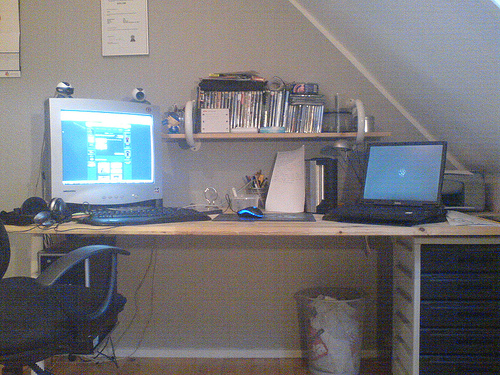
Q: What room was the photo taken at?
A: It was taken at the office.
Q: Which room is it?
A: It is an office.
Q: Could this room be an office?
A: Yes, it is an office.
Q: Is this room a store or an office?
A: It is an office.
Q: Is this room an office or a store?
A: It is an office.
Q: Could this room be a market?
A: No, it is an office.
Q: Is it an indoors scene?
A: Yes, it is indoors.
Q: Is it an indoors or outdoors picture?
A: It is indoors.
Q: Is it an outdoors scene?
A: No, it is indoors.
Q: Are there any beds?
A: No, there are no beds.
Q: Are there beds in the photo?
A: No, there are no beds.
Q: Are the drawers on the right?
A: Yes, the drawers are on the right of the image.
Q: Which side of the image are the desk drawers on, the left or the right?
A: The drawers are on the right of the image.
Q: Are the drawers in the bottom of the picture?
A: Yes, the drawers are in the bottom of the image.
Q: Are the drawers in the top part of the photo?
A: No, the drawers are in the bottom of the image.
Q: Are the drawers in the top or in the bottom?
A: The drawers are in the bottom of the image.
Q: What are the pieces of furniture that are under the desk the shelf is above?
A: The pieces of furniture are drawers.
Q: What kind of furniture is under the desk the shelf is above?
A: The pieces of furniture are drawers.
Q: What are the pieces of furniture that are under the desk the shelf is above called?
A: The pieces of furniture are drawers.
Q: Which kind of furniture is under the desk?
A: The pieces of furniture are drawers.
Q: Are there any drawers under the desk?
A: Yes, there are drawers under the desk.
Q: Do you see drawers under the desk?
A: Yes, there are drawers under the desk.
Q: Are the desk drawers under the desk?
A: Yes, the drawers are under the desk.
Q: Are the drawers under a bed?
A: No, the drawers are under the desk.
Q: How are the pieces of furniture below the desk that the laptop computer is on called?
A: The pieces of furniture are drawers.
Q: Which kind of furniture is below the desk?
A: The pieces of furniture are drawers.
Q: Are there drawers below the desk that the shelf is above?
A: Yes, there are drawers below the desk.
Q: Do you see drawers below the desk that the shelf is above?
A: Yes, there are drawers below the desk.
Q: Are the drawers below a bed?
A: No, the drawers are below the desk.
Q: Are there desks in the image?
A: Yes, there is a desk.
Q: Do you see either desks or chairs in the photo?
A: Yes, there is a desk.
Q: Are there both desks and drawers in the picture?
A: Yes, there are both a desk and drawers.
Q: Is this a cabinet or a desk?
A: This is a desk.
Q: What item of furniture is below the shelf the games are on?
A: The piece of furniture is a desk.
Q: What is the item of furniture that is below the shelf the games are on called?
A: The piece of furniture is a desk.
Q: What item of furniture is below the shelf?
A: The piece of furniture is a desk.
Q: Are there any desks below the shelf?
A: Yes, there is a desk below the shelf.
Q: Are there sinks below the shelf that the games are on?
A: No, there is a desk below the shelf.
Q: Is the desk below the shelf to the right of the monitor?
A: Yes, the desk is below the shelf.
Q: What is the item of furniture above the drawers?
A: The piece of furniture is a desk.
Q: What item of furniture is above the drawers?
A: The piece of furniture is a desk.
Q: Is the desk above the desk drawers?
A: Yes, the desk is above the drawers.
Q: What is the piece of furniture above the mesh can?
A: The piece of furniture is a desk.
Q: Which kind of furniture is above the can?
A: The piece of furniture is a desk.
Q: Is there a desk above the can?
A: Yes, there is a desk above the can.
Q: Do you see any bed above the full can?
A: No, there is a desk above the can.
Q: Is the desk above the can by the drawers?
A: Yes, the desk is above the can.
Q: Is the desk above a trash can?
A: No, the desk is above the can.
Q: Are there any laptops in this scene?
A: Yes, there is a laptop.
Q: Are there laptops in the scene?
A: Yes, there is a laptop.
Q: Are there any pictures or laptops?
A: Yes, there is a laptop.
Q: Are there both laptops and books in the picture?
A: No, there is a laptop but no books.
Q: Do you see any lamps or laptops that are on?
A: Yes, the laptop is on.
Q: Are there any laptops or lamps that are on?
A: Yes, the laptop is on.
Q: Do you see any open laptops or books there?
A: Yes, there is an open laptop.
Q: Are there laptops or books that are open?
A: Yes, the laptop is open.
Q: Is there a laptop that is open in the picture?
A: Yes, there is an open laptop.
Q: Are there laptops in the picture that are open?
A: Yes, there is a laptop that is open.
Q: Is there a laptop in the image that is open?
A: Yes, there is a laptop that is open.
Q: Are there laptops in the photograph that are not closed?
A: Yes, there is a open laptop.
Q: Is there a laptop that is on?
A: Yes, there is a laptop that is on.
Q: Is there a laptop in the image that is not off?
A: Yes, there is a laptop that is on.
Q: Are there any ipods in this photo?
A: No, there are no ipods.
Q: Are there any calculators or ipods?
A: No, there are no ipods or calculators.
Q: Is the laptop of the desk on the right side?
A: Yes, the laptop is on the right of the image.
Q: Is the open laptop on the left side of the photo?
A: No, the laptop is on the right of the image.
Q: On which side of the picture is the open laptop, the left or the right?
A: The laptop computer is on the right of the image.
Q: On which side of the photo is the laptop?
A: The laptop is on the right of the image.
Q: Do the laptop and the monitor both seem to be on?
A: Yes, both the laptop and the monitor are on.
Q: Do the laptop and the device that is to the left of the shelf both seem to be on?
A: Yes, both the laptop and the monitor are on.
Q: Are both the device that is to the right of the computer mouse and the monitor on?
A: Yes, both the laptop and the monitor are on.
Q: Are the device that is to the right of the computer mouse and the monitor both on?
A: Yes, both the laptop and the monitor are on.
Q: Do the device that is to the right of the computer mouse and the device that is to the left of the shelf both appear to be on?
A: Yes, both the laptop and the monitor are on.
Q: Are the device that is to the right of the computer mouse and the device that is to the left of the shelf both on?
A: Yes, both the laptop and the monitor are on.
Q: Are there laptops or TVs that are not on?
A: No, there is a laptop but it is on.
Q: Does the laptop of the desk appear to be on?
A: Yes, the laptop is on.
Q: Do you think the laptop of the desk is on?
A: Yes, the laptop is on.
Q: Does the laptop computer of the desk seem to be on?
A: Yes, the laptop is on.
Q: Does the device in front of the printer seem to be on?
A: Yes, the laptop is on.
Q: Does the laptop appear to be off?
A: No, the laptop is on.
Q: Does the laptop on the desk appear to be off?
A: No, the laptop is on.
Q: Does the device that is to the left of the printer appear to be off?
A: No, the laptop is on.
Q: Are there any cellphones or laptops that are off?
A: No, there is a laptop but it is on.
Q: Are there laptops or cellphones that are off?
A: No, there is a laptop but it is on.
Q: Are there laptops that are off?
A: No, there is a laptop but it is on.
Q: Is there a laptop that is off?
A: No, there is a laptop but it is on.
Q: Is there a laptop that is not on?
A: No, there is a laptop but it is on.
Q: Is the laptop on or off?
A: The laptop is on.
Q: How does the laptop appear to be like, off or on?
A: The laptop is on.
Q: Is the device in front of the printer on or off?
A: The laptop is on.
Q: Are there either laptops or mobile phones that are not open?
A: No, there is a laptop but it is open.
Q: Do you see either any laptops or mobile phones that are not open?
A: No, there is a laptop but it is open.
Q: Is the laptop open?
A: Yes, the laptop is open.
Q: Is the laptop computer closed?
A: No, the laptop computer is open.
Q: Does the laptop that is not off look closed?
A: No, the laptop is open.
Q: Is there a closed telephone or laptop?
A: No, there is a laptop but it is open.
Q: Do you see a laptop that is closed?
A: No, there is a laptop but it is open.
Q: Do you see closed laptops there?
A: No, there is a laptop but it is open.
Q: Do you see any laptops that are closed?
A: No, there is a laptop but it is open.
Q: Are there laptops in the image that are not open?
A: No, there is a laptop but it is open.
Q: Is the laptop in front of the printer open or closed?
A: The laptop computer is open.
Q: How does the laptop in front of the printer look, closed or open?
A: The laptop computer is open.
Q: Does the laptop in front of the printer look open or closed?
A: The laptop computer is open.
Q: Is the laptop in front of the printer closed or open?
A: The laptop computer is open.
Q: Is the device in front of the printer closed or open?
A: The laptop computer is open.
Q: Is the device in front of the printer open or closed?
A: The laptop computer is open.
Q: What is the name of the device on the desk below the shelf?
A: The device is a laptop.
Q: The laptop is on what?
A: The laptop is on the desk.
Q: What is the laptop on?
A: The laptop is on the desk.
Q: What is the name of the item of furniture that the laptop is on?
A: The piece of furniture is a desk.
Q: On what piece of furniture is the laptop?
A: The laptop is on the desk.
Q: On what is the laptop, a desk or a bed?
A: The laptop is on a desk.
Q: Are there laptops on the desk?
A: Yes, there is a laptop on the desk.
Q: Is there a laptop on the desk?
A: Yes, there is a laptop on the desk.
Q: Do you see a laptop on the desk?
A: Yes, there is a laptop on the desk.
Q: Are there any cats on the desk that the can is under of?
A: No, there is a laptop on the desk.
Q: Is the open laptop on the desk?
A: Yes, the laptop is on the desk.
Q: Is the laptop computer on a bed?
A: No, the laptop computer is on the desk.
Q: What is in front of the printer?
A: The laptop is in front of the printer.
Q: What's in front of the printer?
A: The laptop is in front of the printer.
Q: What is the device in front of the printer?
A: The device is a laptop.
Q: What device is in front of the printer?
A: The device is a laptop.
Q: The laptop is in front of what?
A: The laptop is in front of the printer.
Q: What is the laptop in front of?
A: The laptop is in front of the printer.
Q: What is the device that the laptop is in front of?
A: The device is a printer.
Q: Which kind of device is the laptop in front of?
A: The laptop is in front of the printer.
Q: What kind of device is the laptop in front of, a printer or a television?
A: The laptop is in front of a printer.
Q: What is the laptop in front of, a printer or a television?
A: The laptop is in front of a printer.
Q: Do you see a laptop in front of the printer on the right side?
A: Yes, there is a laptop in front of the printer.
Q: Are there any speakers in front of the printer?
A: No, there is a laptop in front of the printer.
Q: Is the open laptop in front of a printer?
A: Yes, the laptop is in front of a printer.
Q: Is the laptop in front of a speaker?
A: No, the laptop is in front of a printer.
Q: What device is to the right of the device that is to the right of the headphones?
A: The device is a laptop.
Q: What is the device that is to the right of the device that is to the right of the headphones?
A: The device is a laptop.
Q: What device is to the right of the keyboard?
A: The device is a laptop.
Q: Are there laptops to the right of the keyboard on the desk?
A: Yes, there is a laptop to the right of the keyboard.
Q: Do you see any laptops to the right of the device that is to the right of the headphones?
A: Yes, there is a laptop to the right of the keyboard.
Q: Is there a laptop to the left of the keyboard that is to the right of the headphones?
A: No, the laptop is to the right of the keyboard.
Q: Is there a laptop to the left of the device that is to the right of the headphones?
A: No, the laptop is to the right of the keyboard.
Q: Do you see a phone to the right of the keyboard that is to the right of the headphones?
A: No, there is a laptop to the right of the keyboard.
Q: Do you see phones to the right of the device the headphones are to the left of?
A: No, there is a laptop to the right of the keyboard.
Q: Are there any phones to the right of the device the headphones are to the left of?
A: No, there is a laptop to the right of the keyboard.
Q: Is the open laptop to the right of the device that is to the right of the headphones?
A: Yes, the laptop computer is to the right of the keyboard.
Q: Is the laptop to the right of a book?
A: No, the laptop is to the right of the keyboard.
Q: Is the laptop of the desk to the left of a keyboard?
A: No, the laptop computer is to the right of a keyboard.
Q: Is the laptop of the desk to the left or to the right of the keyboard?
A: The laptop computer is to the right of the keyboard.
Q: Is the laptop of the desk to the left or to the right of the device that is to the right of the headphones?
A: The laptop computer is to the right of the keyboard.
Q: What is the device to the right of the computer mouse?
A: The device is a laptop.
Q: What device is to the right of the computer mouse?
A: The device is a laptop.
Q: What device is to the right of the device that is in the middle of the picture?
A: The device is a laptop.